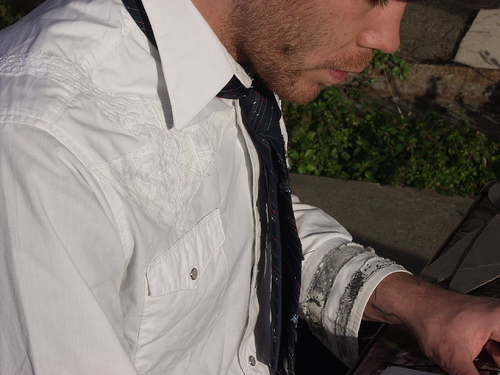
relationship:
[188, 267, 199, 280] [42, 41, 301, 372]
button on shirt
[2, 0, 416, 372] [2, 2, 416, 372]
man in white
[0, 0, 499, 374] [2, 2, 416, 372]
man in white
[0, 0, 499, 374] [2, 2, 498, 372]
man in white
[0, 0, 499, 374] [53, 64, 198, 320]
man in white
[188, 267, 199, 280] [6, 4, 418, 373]
button on shirt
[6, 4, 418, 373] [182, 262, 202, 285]
shirt has button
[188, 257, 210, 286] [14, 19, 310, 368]
button on shirt